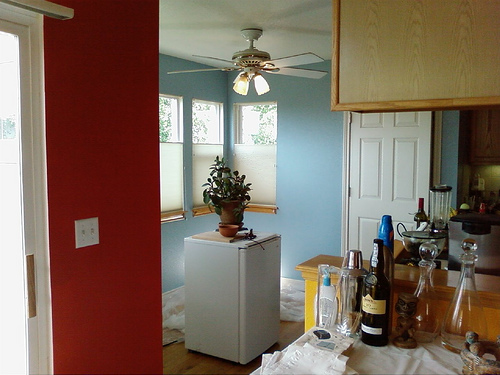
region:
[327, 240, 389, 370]
wine bottle on table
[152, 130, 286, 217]
three frosted windows and a plant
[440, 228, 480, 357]
tall glass drink server on counter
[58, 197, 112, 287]
white light switch on wall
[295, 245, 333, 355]
a bottle of skin so soft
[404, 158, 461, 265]
a clear blender whith black lid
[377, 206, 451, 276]
bowl with lid on counter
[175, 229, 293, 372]
a small mini fridge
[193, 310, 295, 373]
wooden floor beneath fridge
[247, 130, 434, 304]
a white door with rectangle pattern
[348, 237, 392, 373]
wine botle on table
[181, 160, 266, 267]
plant in a brown planter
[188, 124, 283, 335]
plant on top of a mini fridge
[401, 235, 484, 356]
two glass drink servers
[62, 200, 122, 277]
double light switch on wall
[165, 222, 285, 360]
white mini fridge on ground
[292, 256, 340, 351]
clear bottle with blue lid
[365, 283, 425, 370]
a wooden knick knack on table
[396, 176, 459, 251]
black and clear blender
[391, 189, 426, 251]
wine bottle with red top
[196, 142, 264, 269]
a flower in a flower pot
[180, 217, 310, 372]
a small dorm sized refrigerator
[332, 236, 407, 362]
a brown wine bottle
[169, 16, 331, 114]
a ceiling fan with a light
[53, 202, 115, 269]
a white double light switch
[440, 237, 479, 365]
a clear glass bottle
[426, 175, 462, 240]
the top of a blender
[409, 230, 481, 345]
two clear glass bottles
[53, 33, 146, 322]
a wall painted red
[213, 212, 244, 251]
a empty clay bowl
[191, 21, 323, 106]
fan on the roof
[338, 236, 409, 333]
bottle on the counter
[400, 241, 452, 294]
glass on the counter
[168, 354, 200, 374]
floor next to the fridge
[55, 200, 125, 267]
lights on the wall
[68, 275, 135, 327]
red wall next to the light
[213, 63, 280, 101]
lights on the fan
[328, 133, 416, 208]
white door on the wall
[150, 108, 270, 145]
three windows on the wall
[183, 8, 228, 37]
roof of the room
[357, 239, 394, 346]
a bottle of wine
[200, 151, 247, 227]
a potted flowering plant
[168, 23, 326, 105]
a ceiling fan and light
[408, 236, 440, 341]
a clear glass caraffe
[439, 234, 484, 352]
a clear glass caraffe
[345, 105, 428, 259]
a closed white door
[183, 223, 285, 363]
a small white freezer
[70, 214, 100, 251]
a white wall light switch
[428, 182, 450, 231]
an electric blender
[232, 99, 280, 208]
a kitchen window